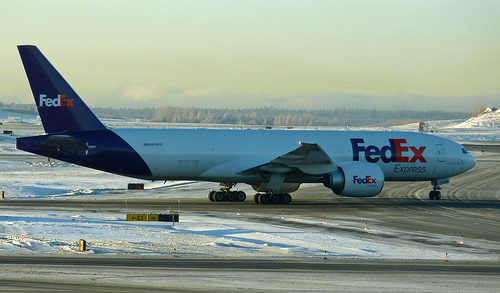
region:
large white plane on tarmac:
[14, 37, 470, 203]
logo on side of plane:
[350, 169, 380, 188]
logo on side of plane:
[345, 130, 433, 167]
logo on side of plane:
[36, 80, 76, 113]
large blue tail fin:
[8, 34, 88, 137]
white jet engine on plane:
[332, 157, 384, 195]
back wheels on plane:
[201, 187, 303, 204]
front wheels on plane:
[425, 187, 447, 201]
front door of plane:
[432, 137, 452, 164]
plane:
[29, 43, 461, 213]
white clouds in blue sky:
[121, 21, 159, 42]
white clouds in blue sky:
[254, 83, 275, 93]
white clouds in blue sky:
[340, 41, 398, 91]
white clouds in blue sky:
[239, 21, 296, 68]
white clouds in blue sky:
[409, 43, 493, 88]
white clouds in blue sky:
[197, 19, 259, 64]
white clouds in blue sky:
[331, 13, 385, 45]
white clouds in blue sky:
[166, 21, 227, 63]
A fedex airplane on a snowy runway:
[8, 33, 487, 221]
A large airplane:
[8, 42, 471, 209]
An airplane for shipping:
[14, 33, 474, 206]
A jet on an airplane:
[324, 158, 386, 200]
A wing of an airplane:
[238, 140, 335, 184]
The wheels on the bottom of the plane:
[206, 187, 449, 205]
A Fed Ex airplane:
[12, 35, 477, 209]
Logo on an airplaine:
[351, 140, 430, 175]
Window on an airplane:
[460, 143, 469, 155]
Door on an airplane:
[432, 140, 447, 163]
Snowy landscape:
[1, 101, 499, 288]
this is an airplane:
[9, 24, 469, 288]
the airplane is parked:
[8, 22, 498, 279]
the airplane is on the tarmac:
[0, 17, 497, 256]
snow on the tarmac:
[30, 184, 487, 288]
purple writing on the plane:
[329, 122, 407, 191]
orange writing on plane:
[388, 119, 433, 181]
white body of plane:
[76, 74, 482, 224]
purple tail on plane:
[2, 25, 157, 191]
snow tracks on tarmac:
[377, 193, 494, 276]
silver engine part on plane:
[312, 154, 357, 199]